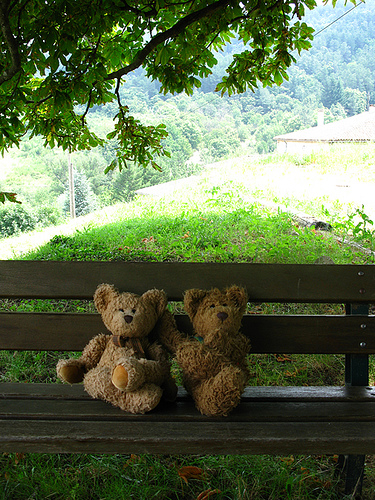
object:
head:
[93, 283, 169, 339]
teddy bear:
[55, 282, 170, 415]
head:
[182, 285, 247, 339]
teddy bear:
[160, 285, 250, 416]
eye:
[209, 303, 215, 308]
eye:
[223, 303, 228, 307]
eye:
[118, 308, 124, 312]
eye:
[131, 307, 136, 313]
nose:
[124, 314, 134, 325]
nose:
[217, 311, 229, 320]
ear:
[184, 289, 202, 317]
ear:
[226, 285, 247, 313]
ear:
[94, 282, 119, 313]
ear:
[142, 287, 165, 316]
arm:
[56, 334, 104, 385]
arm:
[111, 341, 172, 393]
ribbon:
[113, 335, 144, 357]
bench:
[1, 259, 374, 498]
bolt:
[360, 342, 366, 347]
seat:
[1, 386, 374, 455]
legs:
[192, 365, 244, 419]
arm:
[202, 332, 257, 365]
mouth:
[217, 321, 227, 330]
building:
[272, 104, 375, 159]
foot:
[112, 363, 129, 389]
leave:
[214, 80, 224, 92]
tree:
[1, 1, 315, 172]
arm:
[157, 309, 194, 357]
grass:
[2, 207, 375, 499]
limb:
[103, 1, 231, 82]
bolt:
[361, 324, 366, 329]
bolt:
[358, 271, 364, 276]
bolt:
[360, 287, 366, 293]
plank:
[0, 259, 375, 304]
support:
[344, 307, 369, 495]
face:
[195, 295, 243, 338]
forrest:
[0, 0, 374, 237]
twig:
[350, 475, 359, 499]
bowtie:
[192, 336, 205, 344]